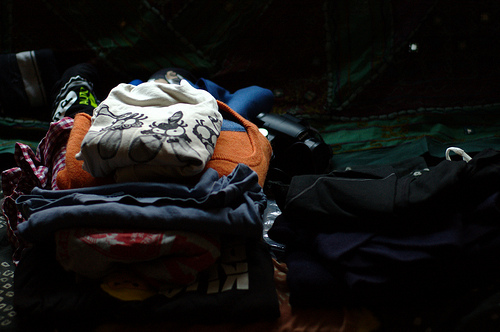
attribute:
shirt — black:
[17, 242, 282, 329]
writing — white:
[186, 257, 253, 294]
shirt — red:
[84, 75, 214, 172]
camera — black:
[252, 107, 394, 168]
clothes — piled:
[2, 67, 277, 330]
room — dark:
[0, 2, 498, 329]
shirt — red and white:
[69, 226, 176, 248]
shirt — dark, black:
[281, 160, 493, 317]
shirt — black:
[279, 141, 497, 238]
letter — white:
[217, 245, 249, 292]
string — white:
[443, 143, 474, 166]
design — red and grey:
[82, 222, 192, 261]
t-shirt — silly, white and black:
[75, 67, 222, 189]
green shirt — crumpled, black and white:
[50, 71, 98, 119]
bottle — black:
[246, 111, 325, 162]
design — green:
[44, 69, 86, 146]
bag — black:
[370, 7, 478, 121]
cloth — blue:
[201, 80, 267, 112]